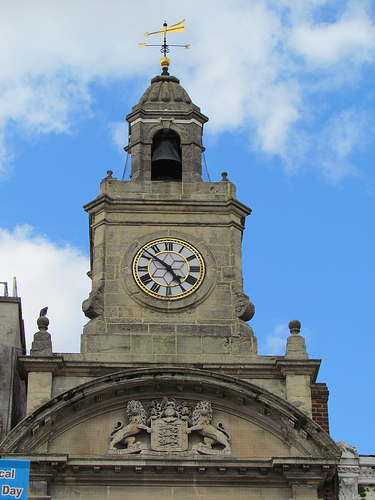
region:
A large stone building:
[19, 128, 360, 499]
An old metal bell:
[150, 138, 189, 180]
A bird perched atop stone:
[39, 304, 49, 318]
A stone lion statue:
[103, 400, 156, 460]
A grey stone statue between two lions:
[150, 397, 193, 454]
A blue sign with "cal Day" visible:
[1, 453, 33, 498]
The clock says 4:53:
[132, 238, 201, 298]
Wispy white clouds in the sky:
[257, 126, 334, 171]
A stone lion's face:
[195, 400, 210, 416]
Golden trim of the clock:
[145, 292, 176, 302]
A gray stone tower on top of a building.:
[72, 48, 257, 476]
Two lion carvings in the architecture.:
[97, 390, 244, 453]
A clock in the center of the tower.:
[108, 221, 213, 316]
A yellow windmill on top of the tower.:
[135, 10, 187, 77]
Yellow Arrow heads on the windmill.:
[130, 24, 156, 51]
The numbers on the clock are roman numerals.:
[127, 238, 203, 291]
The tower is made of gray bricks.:
[96, 311, 240, 351]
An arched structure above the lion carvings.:
[4, 360, 319, 457]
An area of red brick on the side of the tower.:
[315, 381, 331, 426]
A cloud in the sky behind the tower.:
[3, 208, 93, 283]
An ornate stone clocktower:
[26, 126, 347, 489]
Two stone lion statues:
[84, 392, 247, 479]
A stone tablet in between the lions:
[144, 408, 194, 459]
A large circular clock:
[119, 220, 218, 321]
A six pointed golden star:
[148, 250, 190, 287]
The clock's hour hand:
[165, 266, 181, 286]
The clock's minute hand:
[137, 242, 171, 270]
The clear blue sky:
[271, 215, 345, 310]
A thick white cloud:
[0, 241, 75, 308]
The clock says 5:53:
[127, 235, 193, 297]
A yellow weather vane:
[146, 18, 198, 80]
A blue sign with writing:
[0, 458, 36, 498]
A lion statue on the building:
[185, 399, 238, 458]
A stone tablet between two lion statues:
[146, 400, 190, 456]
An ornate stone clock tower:
[13, 180, 345, 497]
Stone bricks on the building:
[95, 317, 239, 360]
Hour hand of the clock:
[165, 266, 188, 291]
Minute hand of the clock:
[138, 246, 168, 264]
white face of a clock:
[135, 236, 201, 297]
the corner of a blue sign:
[0, 458, 53, 498]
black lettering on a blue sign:
[0, 457, 34, 499]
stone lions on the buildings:
[100, 395, 238, 459]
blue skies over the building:
[258, 158, 355, 305]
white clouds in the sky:
[4, 175, 90, 310]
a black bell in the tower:
[143, 128, 189, 179]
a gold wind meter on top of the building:
[124, 13, 201, 90]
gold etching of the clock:
[132, 232, 204, 301]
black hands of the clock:
[147, 247, 183, 284]